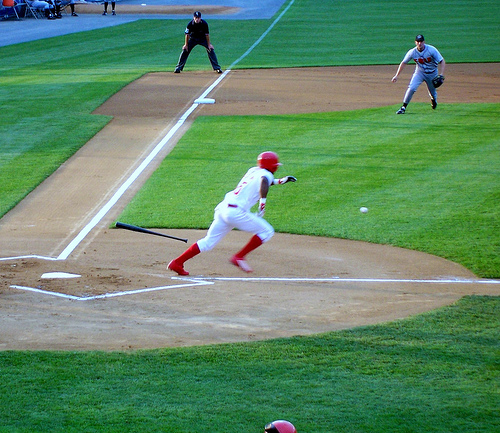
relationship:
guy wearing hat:
[386, 33, 443, 116] [414, 34, 426, 44]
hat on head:
[417, 34, 427, 42] [412, 31, 427, 52]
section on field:
[2, 209, 484, 351] [165, 75, 497, 288]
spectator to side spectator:
[2, 0, 16, 20] [33, 0, 61, 19]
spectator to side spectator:
[2, 0, 16, 20] [103, 1, 117, 15]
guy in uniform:
[376, 26, 493, 137] [392, 50, 459, 104]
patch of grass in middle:
[28, 377, 128, 433] [61, 287, 177, 388]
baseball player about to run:
[159, 139, 307, 312] [82, 162, 342, 383]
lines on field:
[114, 67, 244, 216] [377, 137, 448, 171]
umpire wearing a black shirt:
[137, 12, 235, 73] [174, 50, 212, 72]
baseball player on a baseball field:
[165, 149, 299, 282] [46, 32, 482, 387]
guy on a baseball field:
[386, 33, 443, 116] [87, 164, 342, 339]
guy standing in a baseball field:
[386, 33, 443, 116] [0, 1, 499, 430]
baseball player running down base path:
[165, 149, 299, 282] [111, 253, 499, 294]